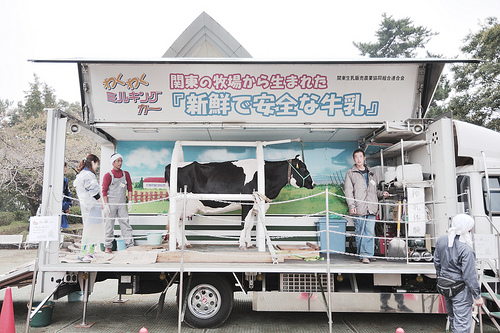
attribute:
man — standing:
[336, 143, 386, 263]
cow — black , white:
[165, 151, 326, 245]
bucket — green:
[26, 301, 52, 326]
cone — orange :
[0, 286, 18, 328]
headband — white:
[107, 153, 123, 161]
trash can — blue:
[314, 213, 347, 256]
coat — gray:
[340, 162, 382, 217]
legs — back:
[153, 203, 201, 253]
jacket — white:
[72, 170, 104, 246]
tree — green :
[376, 19, 495, 117]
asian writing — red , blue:
[73, 61, 371, 148]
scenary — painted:
[118, 145, 365, 222]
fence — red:
[124, 186, 170, 204]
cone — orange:
[2, 287, 22, 331]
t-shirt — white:
[431, 206, 475, 252]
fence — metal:
[52, 192, 441, 262]